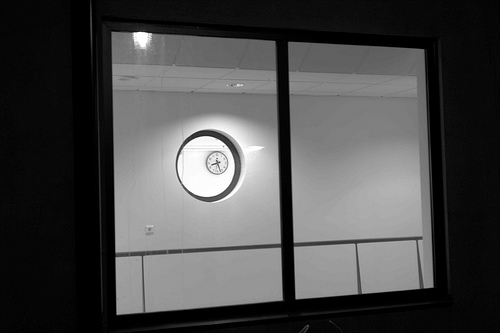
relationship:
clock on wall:
[148, 118, 263, 204] [331, 127, 368, 169]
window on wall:
[173, 131, 194, 202] [331, 127, 368, 169]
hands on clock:
[214, 165, 228, 171] [148, 118, 263, 204]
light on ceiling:
[126, 33, 166, 59] [202, 44, 245, 60]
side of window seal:
[424, 37, 465, 301] [415, 40, 435, 57]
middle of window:
[263, 43, 307, 142] [173, 131, 194, 202]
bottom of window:
[223, 281, 377, 299] [173, 131, 194, 202]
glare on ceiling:
[150, 40, 191, 54] [202, 44, 245, 60]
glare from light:
[150, 40, 191, 54] [126, 33, 166, 59]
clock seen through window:
[148, 118, 263, 204] [173, 131, 194, 202]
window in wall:
[173, 131, 194, 202] [331, 127, 368, 169]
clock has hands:
[148, 118, 263, 204] [214, 165, 228, 171]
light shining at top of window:
[126, 33, 166, 59] [173, 131, 194, 202]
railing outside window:
[318, 229, 399, 251] [173, 131, 194, 202]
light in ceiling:
[126, 33, 166, 59] [202, 44, 245, 60]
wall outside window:
[331, 127, 368, 169] [173, 131, 194, 202]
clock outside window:
[148, 118, 263, 204] [173, 131, 194, 202]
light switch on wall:
[140, 224, 171, 238] [331, 127, 368, 169]